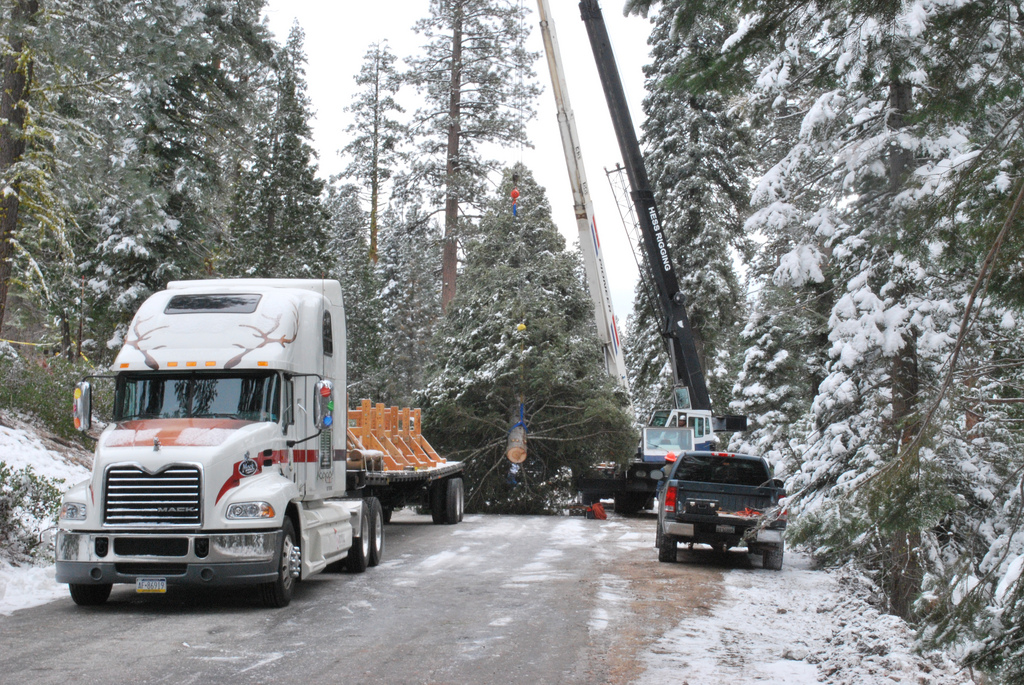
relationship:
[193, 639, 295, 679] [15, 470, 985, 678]
snow on ground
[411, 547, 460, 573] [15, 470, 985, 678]
snow on ground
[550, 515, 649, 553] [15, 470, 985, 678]
snow on ground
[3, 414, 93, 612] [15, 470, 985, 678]
snow on ground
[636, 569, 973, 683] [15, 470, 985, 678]
snow on ground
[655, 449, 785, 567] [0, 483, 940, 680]
truck on road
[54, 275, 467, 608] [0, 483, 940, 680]
truck on road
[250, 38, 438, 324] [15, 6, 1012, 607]
snow on trees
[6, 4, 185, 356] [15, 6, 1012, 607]
snow on trees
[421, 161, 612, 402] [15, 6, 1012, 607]
snow on trees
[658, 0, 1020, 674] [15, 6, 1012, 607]
snow on trees